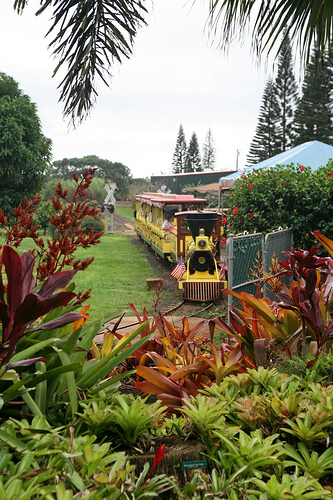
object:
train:
[133, 189, 229, 303]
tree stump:
[119, 439, 212, 490]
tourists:
[160, 210, 178, 235]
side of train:
[132, 189, 177, 260]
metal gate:
[225, 230, 266, 336]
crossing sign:
[103, 181, 117, 207]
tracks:
[107, 204, 133, 232]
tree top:
[220, 159, 331, 231]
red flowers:
[230, 204, 239, 216]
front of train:
[173, 212, 223, 302]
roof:
[134, 189, 213, 211]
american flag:
[168, 259, 186, 280]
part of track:
[157, 295, 210, 324]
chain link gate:
[261, 228, 294, 306]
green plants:
[0, 283, 333, 500]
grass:
[0, 227, 164, 328]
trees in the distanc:
[171, 120, 190, 176]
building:
[148, 167, 242, 192]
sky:
[0, 0, 331, 180]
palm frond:
[92, 63, 112, 88]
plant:
[0, 163, 104, 282]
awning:
[217, 139, 330, 191]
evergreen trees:
[203, 121, 216, 170]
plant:
[0, 243, 87, 375]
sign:
[178, 458, 209, 486]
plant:
[0, 298, 158, 433]